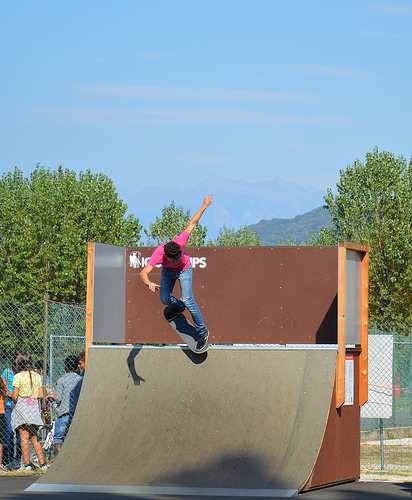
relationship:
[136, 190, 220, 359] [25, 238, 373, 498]
skateboarder on ramp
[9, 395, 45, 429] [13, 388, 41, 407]
jacket tied around waist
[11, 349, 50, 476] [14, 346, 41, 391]
girl has ponytail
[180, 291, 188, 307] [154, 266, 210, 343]
hole in skater's jeans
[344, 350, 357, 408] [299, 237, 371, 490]
sign on side of ramp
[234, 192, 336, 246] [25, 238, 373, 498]
hill behind ramp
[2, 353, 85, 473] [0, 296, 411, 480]
people standing behind fence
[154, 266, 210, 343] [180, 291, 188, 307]
jeans have a hole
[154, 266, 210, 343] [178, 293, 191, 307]
jeans have tear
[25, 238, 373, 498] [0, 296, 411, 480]
ramp surrounded by a gate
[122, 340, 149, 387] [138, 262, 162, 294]
shadow of arm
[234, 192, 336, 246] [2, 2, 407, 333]
mountain in background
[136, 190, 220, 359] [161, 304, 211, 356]
man on skateboard